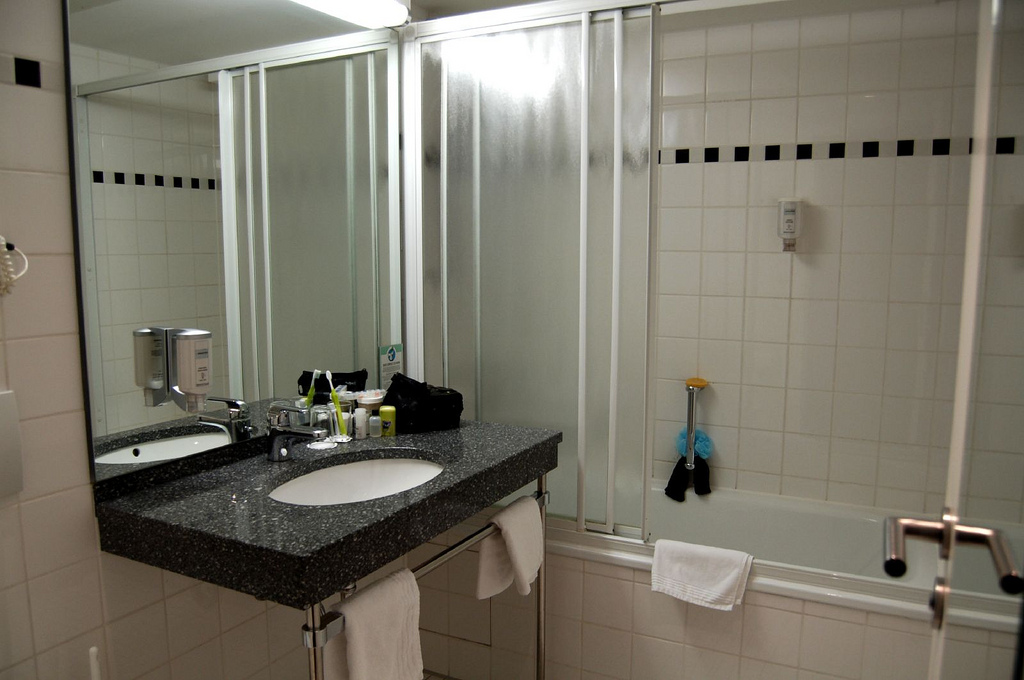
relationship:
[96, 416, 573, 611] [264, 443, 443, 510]
counter around sink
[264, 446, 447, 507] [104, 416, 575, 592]
sink on counter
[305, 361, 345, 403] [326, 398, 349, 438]
toothbrush in cup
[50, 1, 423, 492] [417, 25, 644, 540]
bad mirror reflection of doors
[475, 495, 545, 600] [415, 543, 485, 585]
cloth hanging from bar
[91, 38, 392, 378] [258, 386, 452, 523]
mirror above sink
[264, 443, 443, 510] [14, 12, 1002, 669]
sink in bathroom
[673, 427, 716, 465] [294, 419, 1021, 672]
puff in tub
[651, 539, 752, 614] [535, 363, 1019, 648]
towel draped over bathtub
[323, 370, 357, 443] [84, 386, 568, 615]
toothbrush on countertop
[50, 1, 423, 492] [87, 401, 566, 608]
bad mirror above sink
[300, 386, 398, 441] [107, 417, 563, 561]
personal items on counter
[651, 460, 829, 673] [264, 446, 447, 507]
towel hanging over sink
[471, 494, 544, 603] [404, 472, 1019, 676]
cloth on tub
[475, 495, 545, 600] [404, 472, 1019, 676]
cloth on tub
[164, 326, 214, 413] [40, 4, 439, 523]
dispenser on mirror